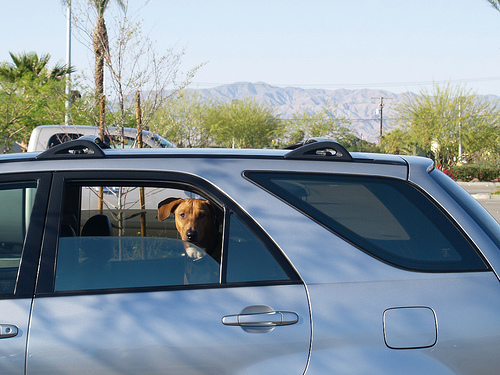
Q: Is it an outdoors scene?
A: Yes, it is outdoors.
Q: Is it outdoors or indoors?
A: It is outdoors.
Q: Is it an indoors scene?
A: No, it is outdoors.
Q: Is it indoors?
A: No, it is outdoors.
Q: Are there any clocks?
A: No, there are no clocks.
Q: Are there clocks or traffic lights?
A: No, there are no clocks or traffic lights.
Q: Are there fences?
A: No, there are no fences.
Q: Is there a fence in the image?
A: No, there are no fences.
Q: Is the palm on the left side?
A: Yes, the palm is on the left of the image.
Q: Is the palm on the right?
A: No, the palm is on the left of the image.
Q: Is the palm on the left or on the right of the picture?
A: The palm is on the left of the image.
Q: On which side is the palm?
A: The palm is on the left of the image.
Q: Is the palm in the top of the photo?
A: Yes, the palm is in the top of the image.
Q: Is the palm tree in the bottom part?
A: No, the palm tree is in the top of the image.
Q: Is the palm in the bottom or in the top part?
A: The palm is in the top of the image.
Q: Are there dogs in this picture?
A: Yes, there is a dog.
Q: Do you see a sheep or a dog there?
A: Yes, there is a dog.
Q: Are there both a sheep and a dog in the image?
A: No, there is a dog but no sheep.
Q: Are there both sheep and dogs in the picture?
A: No, there is a dog but no sheep.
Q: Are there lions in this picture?
A: No, there are no lions.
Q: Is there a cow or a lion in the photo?
A: No, there are no lions or cows.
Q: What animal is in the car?
A: The dog is in the car.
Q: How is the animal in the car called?
A: The animal is a dog.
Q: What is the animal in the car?
A: The animal is a dog.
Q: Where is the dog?
A: The dog is in the car.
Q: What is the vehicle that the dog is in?
A: The vehicle is a car.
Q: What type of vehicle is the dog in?
A: The dog is in the car.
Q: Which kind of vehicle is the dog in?
A: The dog is in the car.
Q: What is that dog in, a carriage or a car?
A: The dog is in a car.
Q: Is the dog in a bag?
A: No, the dog is in a car.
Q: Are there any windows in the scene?
A: Yes, there is a window.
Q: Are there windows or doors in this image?
A: Yes, there is a window.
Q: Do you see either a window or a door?
A: Yes, there is a window.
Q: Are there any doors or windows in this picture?
A: Yes, there is a window.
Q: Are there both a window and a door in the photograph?
A: Yes, there are both a window and a door.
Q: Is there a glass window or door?
A: Yes, there is a glass window.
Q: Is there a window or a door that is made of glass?
A: Yes, the window is made of glass.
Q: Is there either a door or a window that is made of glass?
A: Yes, the window is made of glass.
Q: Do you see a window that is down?
A: Yes, there is a window that is down.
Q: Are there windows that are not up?
A: Yes, there is a window that is down.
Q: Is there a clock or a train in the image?
A: No, there are no clocks or trains.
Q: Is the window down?
A: Yes, the window is down.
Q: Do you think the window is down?
A: Yes, the window is down.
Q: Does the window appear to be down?
A: Yes, the window is down.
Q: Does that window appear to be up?
A: No, the window is down.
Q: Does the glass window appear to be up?
A: No, the window is down.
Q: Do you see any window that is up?
A: No, there is a window but it is down.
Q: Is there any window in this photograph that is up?
A: No, there is a window but it is down.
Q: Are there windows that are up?
A: No, there is a window but it is down.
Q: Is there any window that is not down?
A: No, there is a window but it is down.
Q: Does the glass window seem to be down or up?
A: The window is down.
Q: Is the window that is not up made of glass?
A: Yes, the window is made of glass.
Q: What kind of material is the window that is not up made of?
A: The window is made of glass.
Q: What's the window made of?
A: The window is made of glass.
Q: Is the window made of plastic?
A: No, the window is made of glass.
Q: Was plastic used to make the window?
A: No, the window is made of glass.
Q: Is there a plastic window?
A: No, there is a window but it is made of glass.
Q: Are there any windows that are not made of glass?
A: No, there is a window but it is made of glass.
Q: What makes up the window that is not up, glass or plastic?
A: The window is made of glass.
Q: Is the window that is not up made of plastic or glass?
A: The window is made of glass.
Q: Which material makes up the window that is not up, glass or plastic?
A: The window is made of glass.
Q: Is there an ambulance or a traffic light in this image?
A: No, there are no ambulances or traffic lights.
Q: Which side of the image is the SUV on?
A: The SUV is on the left of the image.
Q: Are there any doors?
A: Yes, there is a door.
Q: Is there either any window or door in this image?
A: Yes, there is a door.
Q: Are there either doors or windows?
A: Yes, there is a door.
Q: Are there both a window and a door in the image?
A: Yes, there are both a door and a window.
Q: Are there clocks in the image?
A: No, there are no clocks.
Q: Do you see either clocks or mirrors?
A: No, there are no clocks or mirrors.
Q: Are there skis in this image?
A: No, there are no skis.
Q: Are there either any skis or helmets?
A: No, there are no skis or helmets.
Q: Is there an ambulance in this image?
A: No, there are no ambulances.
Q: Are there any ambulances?
A: No, there are no ambulances.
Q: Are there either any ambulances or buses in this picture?
A: No, there are no ambulances or buses.